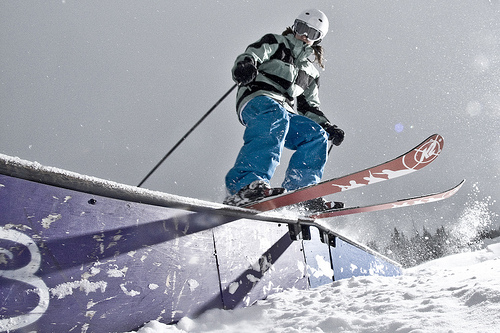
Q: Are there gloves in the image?
A: Yes, there are gloves.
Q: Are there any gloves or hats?
A: Yes, there are gloves.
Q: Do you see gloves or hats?
A: Yes, there are gloves.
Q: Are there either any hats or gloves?
A: Yes, there are gloves.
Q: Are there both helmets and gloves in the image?
A: Yes, there are both gloves and a helmet.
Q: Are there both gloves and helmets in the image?
A: Yes, there are both gloves and a helmet.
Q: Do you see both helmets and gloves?
A: Yes, there are both gloves and a helmet.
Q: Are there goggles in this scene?
A: Yes, there are goggles.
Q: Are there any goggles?
A: Yes, there are goggles.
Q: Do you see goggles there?
A: Yes, there are goggles.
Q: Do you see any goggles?
A: Yes, there are goggles.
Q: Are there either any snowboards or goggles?
A: Yes, there are goggles.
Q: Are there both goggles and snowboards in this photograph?
A: No, there are goggles but no snowboards.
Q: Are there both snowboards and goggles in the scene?
A: No, there are goggles but no snowboards.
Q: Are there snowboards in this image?
A: No, there are no snowboards.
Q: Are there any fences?
A: No, there are no fences.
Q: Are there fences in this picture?
A: No, there are no fences.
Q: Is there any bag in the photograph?
A: No, there are no bags.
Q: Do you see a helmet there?
A: Yes, there is a helmet.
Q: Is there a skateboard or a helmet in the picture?
A: Yes, there is a helmet.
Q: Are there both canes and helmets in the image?
A: No, there is a helmet but no canes.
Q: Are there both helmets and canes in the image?
A: No, there is a helmet but no canes.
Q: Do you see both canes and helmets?
A: No, there is a helmet but no canes.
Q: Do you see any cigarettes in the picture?
A: No, there are no cigarettes.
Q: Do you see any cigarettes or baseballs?
A: No, there are no cigarettes or baseballs.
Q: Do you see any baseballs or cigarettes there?
A: No, there are no cigarettes or baseballs.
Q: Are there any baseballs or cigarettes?
A: No, there are no cigarettes or baseballs.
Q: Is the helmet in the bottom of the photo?
A: No, the helmet is in the top of the image.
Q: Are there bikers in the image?
A: No, there are no bikers.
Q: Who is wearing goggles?
A: The girl is wearing goggles.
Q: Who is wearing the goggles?
A: The girl is wearing goggles.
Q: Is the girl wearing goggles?
A: Yes, the girl is wearing goggles.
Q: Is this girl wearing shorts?
A: No, the girl is wearing goggles.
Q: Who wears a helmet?
A: The girl wears a helmet.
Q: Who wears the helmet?
A: The girl wears a helmet.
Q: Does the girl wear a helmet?
A: Yes, the girl wears a helmet.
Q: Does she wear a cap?
A: No, the girl wears a helmet.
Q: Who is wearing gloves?
A: The girl is wearing gloves.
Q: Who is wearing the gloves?
A: The girl is wearing gloves.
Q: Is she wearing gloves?
A: Yes, the girl is wearing gloves.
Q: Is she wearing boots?
A: No, the girl is wearing gloves.